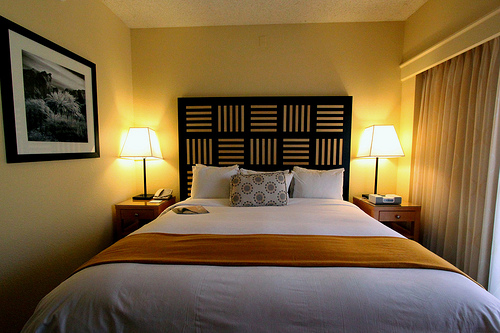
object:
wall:
[136, 22, 409, 198]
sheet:
[62, 232, 484, 288]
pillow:
[191, 164, 239, 199]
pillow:
[291, 166, 346, 200]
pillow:
[238, 168, 293, 204]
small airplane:
[177, 95, 352, 169]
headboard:
[177, 95, 352, 201]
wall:
[402, 2, 497, 57]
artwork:
[0, 15, 101, 164]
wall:
[0, 0, 132, 330]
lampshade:
[358, 125, 405, 158]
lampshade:
[120, 127, 162, 160]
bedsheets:
[23, 198, 500, 333]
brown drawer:
[120, 209, 155, 220]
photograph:
[7, 29, 95, 154]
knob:
[396, 215, 401, 219]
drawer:
[379, 211, 416, 222]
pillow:
[229, 172, 288, 206]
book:
[172, 205, 210, 214]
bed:
[20, 95, 499, 333]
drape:
[407, 38, 498, 298]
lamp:
[357, 125, 405, 158]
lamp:
[120, 127, 163, 160]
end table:
[352, 195, 421, 241]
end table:
[115, 196, 175, 239]